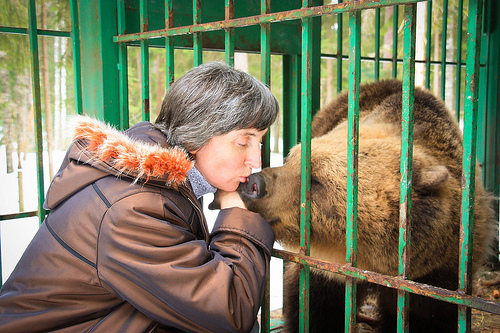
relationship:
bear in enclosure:
[230, 76, 499, 331] [293, 57, 493, 312]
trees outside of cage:
[1, 8, 78, 208] [60, 2, 224, 74]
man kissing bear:
[2, 58, 283, 330] [239, 80, 498, 332]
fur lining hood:
[59, 112, 199, 188] [33, 99, 200, 219]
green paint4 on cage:
[458, 142, 473, 296] [0, 22, 497, 329]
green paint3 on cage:
[399, 46, 411, 281] [0, 22, 497, 329]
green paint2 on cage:
[346, 150, 357, 269] [0, 22, 497, 329]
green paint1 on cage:
[301, 152, 311, 254] [0, 22, 497, 329]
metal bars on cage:
[121, 21, 129, 131] [0, 22, 497, 329]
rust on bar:
[325, 257, 416, 291] [344, 2, 363, 319]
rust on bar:
[325, 257, 416, 291] [392, 7, 411, 322]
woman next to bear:
[9, 62, 288, 327] [292, 141, 474, 301]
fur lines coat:
[109, 139, 177, 182] [0, 115, 273, 331]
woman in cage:
[9, 62, 288, 327] [7, 7, 477, 321]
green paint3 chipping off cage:
[395, 46, 410, 281] [0, 3, 500, 333]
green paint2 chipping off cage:
[348, 150, 355, 269] [0, 3, 500, 333]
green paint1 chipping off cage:
[297, 152, 311, 254] [0, 3, 500, 333]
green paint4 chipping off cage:
[461, 142, 468, 296] [0, 3, 500, 333]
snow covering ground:
[1, 145, 55, 257] [8, 146, 73, 270]